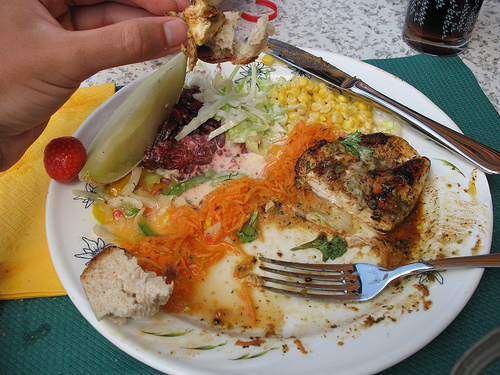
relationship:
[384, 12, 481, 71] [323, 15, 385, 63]
glass on table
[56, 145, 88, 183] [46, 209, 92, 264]
strawberry on plate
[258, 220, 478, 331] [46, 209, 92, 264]
fork on plate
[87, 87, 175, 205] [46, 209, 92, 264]
pickle on plate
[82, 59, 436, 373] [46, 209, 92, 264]
food on plate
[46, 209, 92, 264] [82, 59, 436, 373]
plate has food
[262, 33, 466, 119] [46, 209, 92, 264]
knife on plate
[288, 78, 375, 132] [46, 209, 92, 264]
corn on plate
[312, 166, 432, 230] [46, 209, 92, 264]
chicken on plate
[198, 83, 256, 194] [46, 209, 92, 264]
cabbage on plate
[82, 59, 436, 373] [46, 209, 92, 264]
carrot on plate